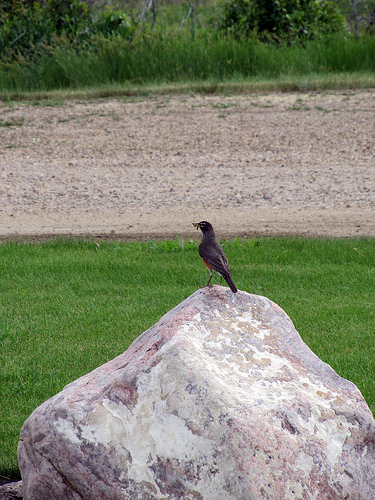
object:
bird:
[192, 221, 238, 294]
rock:
[16, 284, 374, 500]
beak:
[192, 222, 200, 228]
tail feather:
[223, 274, 238, 293]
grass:
[0, 237, 375, 479]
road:
[0, 89, 374, 236]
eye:
[200, 223, 206, 228]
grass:
[0, 32, 373, 101]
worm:
[197, 226, 199, 230]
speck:
[51, 415, 83, 447]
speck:
[240, 347, 272, 371]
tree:
[344, 1, 374, 38]